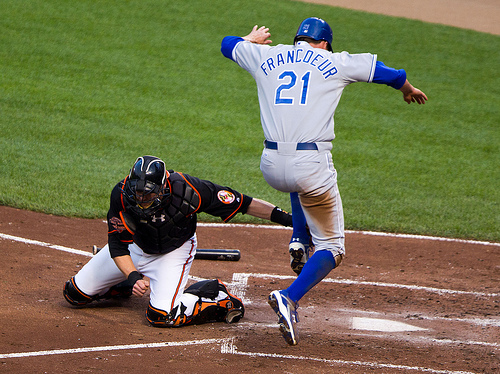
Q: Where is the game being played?
A: Baseball field.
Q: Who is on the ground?
A: The catcher.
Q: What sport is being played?
A: Baseball.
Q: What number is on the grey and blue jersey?
A: 21.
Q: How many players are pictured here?
A: Two.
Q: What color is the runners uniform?
A: Blue and gray.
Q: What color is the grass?
A: Green.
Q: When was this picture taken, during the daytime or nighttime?
A: Daytime.